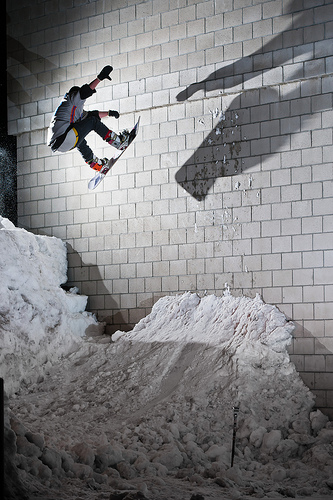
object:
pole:
[226, 404, 244, 457]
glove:
[97, 63, 117, 81]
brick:
[9, 16, 332, 395]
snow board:
[66, 113, 158, 182]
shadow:
[171, 1, 332, 204]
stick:
[229, 405, 238, 467]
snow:
[0, 216, 330, 497]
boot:
[104, 127, 131, 151]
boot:
[84, 155, 107, 172]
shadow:
[189, 19, 312, 191]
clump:
[93, 440, 125, 467]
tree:
[1, 143, 19, 219]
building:
[7, 4, 332, 418]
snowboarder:
[42, 61, 134, 175]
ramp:
[111, 283, 288, 455]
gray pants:
[71, 117, 105, 141]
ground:
[4, 357, 327, 495]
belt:
[67, 123, 91, 157]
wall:
[3, 6, 331, 381]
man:
[45, 64, 123, 163]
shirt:
[44, 90, 86, 134]